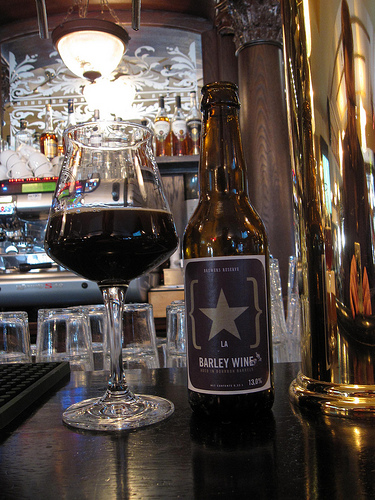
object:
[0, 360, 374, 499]
table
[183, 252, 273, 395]
label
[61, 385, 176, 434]
base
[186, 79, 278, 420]
bear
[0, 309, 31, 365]
glasses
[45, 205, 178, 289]
wine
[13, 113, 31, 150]
bottles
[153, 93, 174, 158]
booze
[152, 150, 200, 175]
shelf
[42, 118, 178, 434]
glass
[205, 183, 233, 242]
glass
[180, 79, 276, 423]
bottle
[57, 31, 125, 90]
light